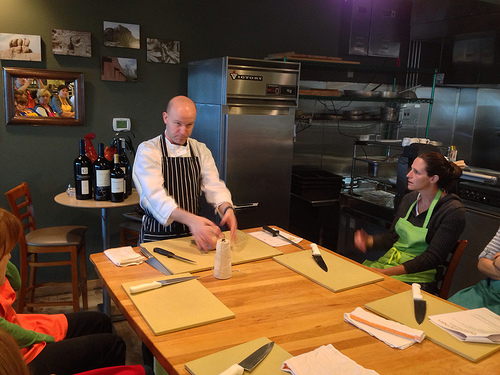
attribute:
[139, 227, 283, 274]
cutting board — plastic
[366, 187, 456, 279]
apron — green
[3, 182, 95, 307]
chair — brown, wooden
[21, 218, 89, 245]
seat — tan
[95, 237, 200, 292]
towel — white, folded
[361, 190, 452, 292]
apron — green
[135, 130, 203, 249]
striped apron — black, white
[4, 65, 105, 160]
frame — brown, wooden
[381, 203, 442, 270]
apron — green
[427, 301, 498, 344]
papers — stapled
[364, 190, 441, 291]
apron — green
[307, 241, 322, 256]
handle — white, plastic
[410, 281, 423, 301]
handle — white, plastic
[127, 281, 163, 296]
handle — white, plastic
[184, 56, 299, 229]
freezer — commercial, stainless steel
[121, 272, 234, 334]
board — tan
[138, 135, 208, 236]
apron — striped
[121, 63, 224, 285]
man — bald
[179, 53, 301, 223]
commercial fridge — stainless steel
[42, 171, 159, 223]
table — circular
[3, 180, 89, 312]
chair — empty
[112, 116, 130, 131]
thermostat — white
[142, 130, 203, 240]
apron — black, white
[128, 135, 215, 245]
apron — striped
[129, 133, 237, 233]
shirt — white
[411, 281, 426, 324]
knife — white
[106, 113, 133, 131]
thermostat — white, wall mounted, digital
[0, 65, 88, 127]
frame — wooden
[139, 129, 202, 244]
apron — black, white, striped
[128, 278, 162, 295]
handle — white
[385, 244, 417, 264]
tie — yellow